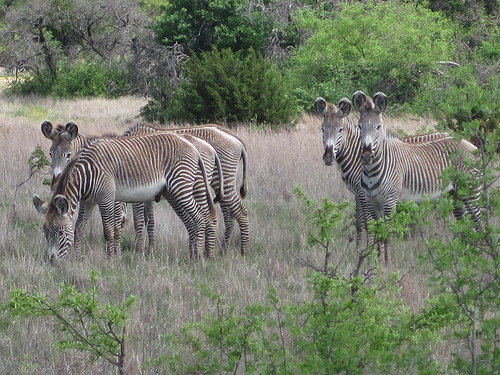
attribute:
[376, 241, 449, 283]
grass — dry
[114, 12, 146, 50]
branches — bare, tree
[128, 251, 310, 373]
grass — dry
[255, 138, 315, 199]
grass field — dry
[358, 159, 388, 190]
stripe pattern — brown and white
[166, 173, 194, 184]
stripe — brown, white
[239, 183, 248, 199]
tip — bushy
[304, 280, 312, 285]
leaf — small, green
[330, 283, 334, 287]
leaf — small, green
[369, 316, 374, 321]
leaf — small, green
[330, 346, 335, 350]
leaf — small, green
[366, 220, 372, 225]
leaf — small, green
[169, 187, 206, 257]
legs — hind legs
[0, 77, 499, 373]
grass — dry, tall, brown